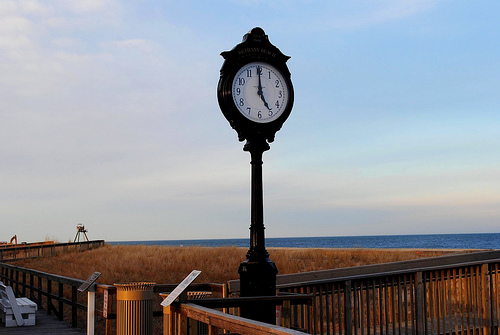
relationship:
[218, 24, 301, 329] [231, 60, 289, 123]
clock has face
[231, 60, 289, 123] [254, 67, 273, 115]
face has hands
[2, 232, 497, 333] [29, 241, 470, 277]
ground has grass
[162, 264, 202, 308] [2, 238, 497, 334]
sign on board walk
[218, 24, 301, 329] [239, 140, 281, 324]
clock has pole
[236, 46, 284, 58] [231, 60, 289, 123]
writing above face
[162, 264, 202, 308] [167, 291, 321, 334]
sign on railing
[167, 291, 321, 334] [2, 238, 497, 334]
railing on board walk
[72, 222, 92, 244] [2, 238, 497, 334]
contraption on board walk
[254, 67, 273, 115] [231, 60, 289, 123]
hands on face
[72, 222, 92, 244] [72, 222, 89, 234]
contraption has top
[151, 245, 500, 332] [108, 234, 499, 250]
walkway to water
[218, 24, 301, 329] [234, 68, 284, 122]
clock has numbers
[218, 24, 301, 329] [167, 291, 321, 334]
clock behind railing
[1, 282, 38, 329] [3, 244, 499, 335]
chair behind fence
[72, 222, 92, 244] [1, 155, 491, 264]
contraption in distance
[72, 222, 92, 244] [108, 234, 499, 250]
contraption near water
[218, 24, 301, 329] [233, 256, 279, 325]
clock has stand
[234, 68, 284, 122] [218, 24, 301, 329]
numbers on clock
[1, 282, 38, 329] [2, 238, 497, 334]
chair on board walk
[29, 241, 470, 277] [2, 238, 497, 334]
grass in front of board walk